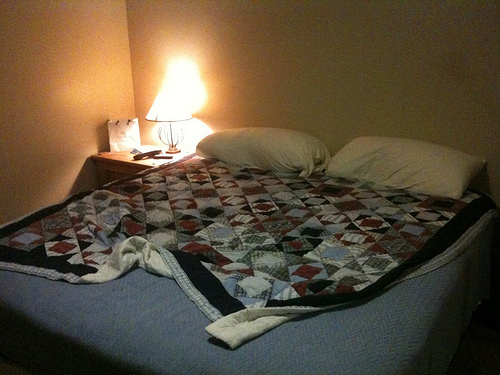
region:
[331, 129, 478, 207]
white pillow on bed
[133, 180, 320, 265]
bedspread on the bed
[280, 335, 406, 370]
blue blanket on the bed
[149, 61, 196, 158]
lamp sitting on table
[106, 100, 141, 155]
white gift bag on table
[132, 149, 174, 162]
two remotes on table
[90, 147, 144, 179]
table beside the bed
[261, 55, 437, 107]
tan wall behind bed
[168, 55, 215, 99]
illusium of light turned on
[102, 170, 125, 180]
drawer on table by bed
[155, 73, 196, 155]
A lamp on a stand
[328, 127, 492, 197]
Pillow on a bed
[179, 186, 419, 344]
Quilt on a bed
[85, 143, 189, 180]
A stand beside bed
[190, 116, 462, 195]
A couple of pillows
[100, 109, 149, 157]
A bag on a stand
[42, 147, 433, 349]
a unmade bed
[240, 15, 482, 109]
A yellow wall behind a bed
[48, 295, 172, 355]
A gray blanket on a bed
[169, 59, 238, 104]
A shadow behid the light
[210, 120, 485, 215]
two white pillows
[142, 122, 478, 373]
two white pillows on the bed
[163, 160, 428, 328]
colorful quilt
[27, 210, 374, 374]
blue sheets on bed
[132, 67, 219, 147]
lamp near the bed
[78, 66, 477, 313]
nightstand near the bed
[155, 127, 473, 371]
quilt with many patterns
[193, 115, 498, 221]
white pillows on top of the quilt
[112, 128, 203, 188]
remote control on night stand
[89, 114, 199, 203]
tan nightstand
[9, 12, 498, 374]
A bedroom.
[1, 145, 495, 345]
A quilt spread out on top of a bed.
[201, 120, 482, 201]
White pillows.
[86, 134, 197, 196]
A wooden night stand.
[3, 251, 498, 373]
Light blue colored sheets on the bed.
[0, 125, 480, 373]
A bed.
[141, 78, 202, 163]
A lamp turned on.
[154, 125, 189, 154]
A lamp base.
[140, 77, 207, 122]
A lit up lamp shade.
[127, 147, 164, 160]
A black remote controller.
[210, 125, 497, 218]
Pair of white pillows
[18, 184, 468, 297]
Red, Blue, White and Plad Quilts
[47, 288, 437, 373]
Blue bed Quilt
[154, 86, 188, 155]
Lite Bedside table lamp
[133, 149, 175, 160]
Black T.V. Remote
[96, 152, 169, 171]
Part of bedside table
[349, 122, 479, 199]
Fluffy white bed pillow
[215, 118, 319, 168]
Fluffy white bed pillow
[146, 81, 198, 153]
Bedside table Lamp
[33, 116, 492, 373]
Bed with pillows and quilts